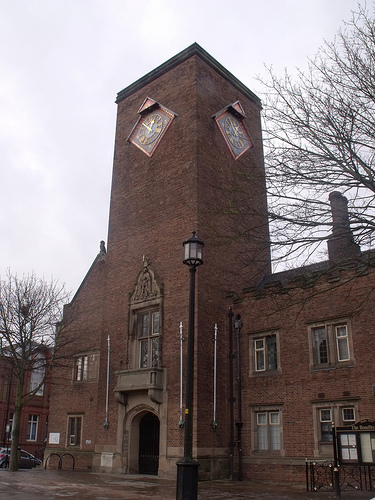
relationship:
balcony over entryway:
[110, 367, 166, 404] [118, 401, 167, 475]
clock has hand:
[125, 97, 178, 158] [145, 117, 157, 133]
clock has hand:
[125, 97, 178, 158] [139, 119, 151, 130]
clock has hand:
[209, 97, 255, 159] [228, 117, 238, 136]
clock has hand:
[125, 97, 178, 158] [231, 124, 238, 136]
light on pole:
[182, 230, 204, 267] [170, 266, 205, 499]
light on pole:
[182, 230, 204, 267] [176, 266, 199, 498]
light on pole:
[182, 230, 204, 267] [183, 262, 200, 457]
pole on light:
[174, 268, 203, 498] [182, 230, 204, 267]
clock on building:
[125, 97, 178, 158] [89, 42, 372, 333]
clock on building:
[125, 97, 178, 158] [41, 36, 363, 484]